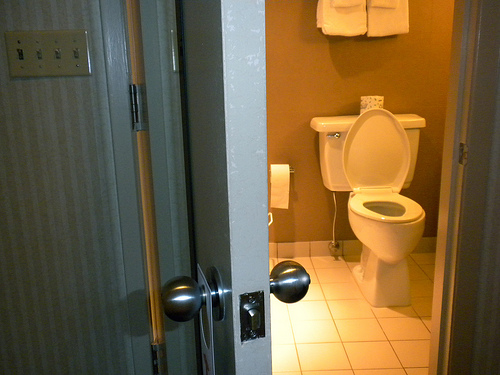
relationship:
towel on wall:
[314, 2, 368, 39] [265, 1, 455, 257]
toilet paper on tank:
[359, 93, 383, 117] [310, 113, 427, 191]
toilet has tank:
[309, 112, 426, 307] [310, 113, 427, 191]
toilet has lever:
[309, 112, 426, 307] [328, 133, 342, 140]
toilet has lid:
[309, 112, 426, 307] [341, 107, 413, 195]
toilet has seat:
[309, 112, 426, 307] [347, 190, 424, 224]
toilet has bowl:
[309, 112, 426, 307] [346, 192, 427, 264]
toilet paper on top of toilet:
[359, 93, 383, 117] [309, 112, 426, 307]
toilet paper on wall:
[269, 162, 292, 212] [265, 1, 455, 257]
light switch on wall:
[2, 28, 94, 82] [0, 5, 199, 373]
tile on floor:
[297, 341, 354, 373] [268, 252, 438, 373]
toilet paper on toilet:
[359, 93, 383, 117] [309, 112, 426, 307]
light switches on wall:
[2, 28, 94, 82] [0, 5, 199, 373]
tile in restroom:
[297, 341, 354, 373] [263, 0, 456, 373]